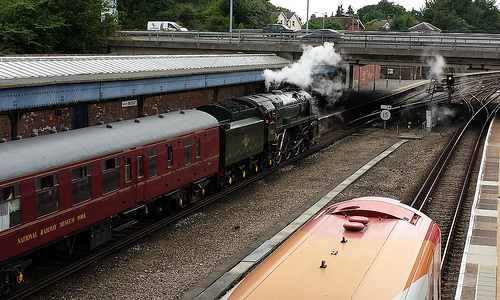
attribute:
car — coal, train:
[299, 23, 339, 40]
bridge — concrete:
[109, 29, 499, 70]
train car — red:
[0, 106, 222, 295]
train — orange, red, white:
[215, 194, 450, 297]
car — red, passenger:
[7, 119, 218, 244]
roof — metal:
[1, 48, 289, 85]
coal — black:
[213, 93, 253, 114]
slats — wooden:
[408, 113, 485, 245]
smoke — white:
[257, 41, 344, 101]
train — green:
[212, 90, 321, 182]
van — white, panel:
[145, 18, 187, 33]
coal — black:
[218, 96, 253, 112]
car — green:
[202, 96, 269, 167]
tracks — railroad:
[241, 66, 492, 298]